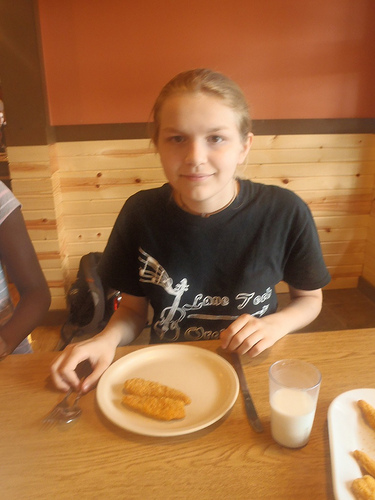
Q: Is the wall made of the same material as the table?
A: Yes, both the wall and the table are made of wood.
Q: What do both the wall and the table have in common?
A: The material, both the wall and the table are wooden.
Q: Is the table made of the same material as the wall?
A: Yes, both the table and the wall are made of wood.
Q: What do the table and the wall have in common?
A: The material, both the table and the wall are wooden.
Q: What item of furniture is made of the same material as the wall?
A: The table is made of the same material as the wall.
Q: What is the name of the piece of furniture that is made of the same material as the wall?
A: The piece of furniture is a table.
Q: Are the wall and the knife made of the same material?
A: No, the wall is made of wood and the knife is made of metal.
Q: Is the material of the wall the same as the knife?
A: No, the wall is made of wood and the knife is made of metal.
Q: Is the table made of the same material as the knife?
A: No, the table is made of wood and the knife is made of metal.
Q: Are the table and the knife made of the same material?
A: No, the table is made of wood and the knife is made of metal.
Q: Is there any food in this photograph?
A: Yes, there is food.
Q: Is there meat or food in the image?
A: Yes, there is food.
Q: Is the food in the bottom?
A: Yes, the food is in the bottom of the image.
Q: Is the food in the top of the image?
A: No, the food is in the bottom of the image.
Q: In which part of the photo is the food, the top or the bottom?
A: The food is in the bottom of the image.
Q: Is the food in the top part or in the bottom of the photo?
A: The food is in the bottom of the image.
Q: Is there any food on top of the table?
A: Yes, there is food on top of the table.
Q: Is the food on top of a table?
A: Yes, the food is on top of a table.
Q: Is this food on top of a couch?
A: No, the food is on top of a table.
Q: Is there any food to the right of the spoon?
A: Yes, there is food to the right of the spoon.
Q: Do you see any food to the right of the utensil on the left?
A: Yes, there is food to the right of the spoon.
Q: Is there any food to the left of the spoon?
A: No, the food is to the right of the spoon.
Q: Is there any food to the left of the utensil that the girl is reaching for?
A: No, the food is to the right of the spoon.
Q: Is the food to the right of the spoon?
A: Yes, the food is to the right of the spoon.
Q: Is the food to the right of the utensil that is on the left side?
A: Yes, the food is to the right of the spoon.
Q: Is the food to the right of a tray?
A: No, the food is to the right of the spoon.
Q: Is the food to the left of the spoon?
A: No, the food is to the right of the spoon.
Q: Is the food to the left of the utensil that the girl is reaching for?
A: No, the food is to the right of the spoon.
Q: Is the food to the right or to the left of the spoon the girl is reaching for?
A: The food is to the right of the spoon.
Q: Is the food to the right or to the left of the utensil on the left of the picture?
A: The food is to the right of the spoon.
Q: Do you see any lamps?
A: No, there are no lamps.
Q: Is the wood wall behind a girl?
A: Yes, the wall is behind a girl.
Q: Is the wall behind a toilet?
A: No, the wall is behind a girl.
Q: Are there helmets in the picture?
A: No, there are no helmets.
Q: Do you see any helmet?
A: No, there are no helmets.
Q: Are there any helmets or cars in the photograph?
A: No, there are no helmets or cars.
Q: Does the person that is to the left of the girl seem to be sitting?
A: Yes, the person is sitting.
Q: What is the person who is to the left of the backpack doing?
A: The person is sitting.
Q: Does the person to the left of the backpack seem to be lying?
A: No, the person is sitting.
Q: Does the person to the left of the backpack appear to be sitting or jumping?
A: The person is sitting.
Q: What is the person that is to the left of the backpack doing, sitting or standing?
A: The person is sitting.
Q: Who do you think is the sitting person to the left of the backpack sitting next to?
A: The person is sitting next to the girl.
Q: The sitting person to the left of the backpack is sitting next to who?
A: The person is sitting next to the girl.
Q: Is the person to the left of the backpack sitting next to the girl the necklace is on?
A: Yes, the person is sitting next to the girl.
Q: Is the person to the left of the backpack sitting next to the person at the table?
A: Yes, the person is sitting next to the girl.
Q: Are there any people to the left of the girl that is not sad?
A: Yes, there is a person to the left of the girl.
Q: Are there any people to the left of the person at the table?
A: Yes, there is a person to the left of the girl.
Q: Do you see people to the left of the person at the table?
A: Yes, there is a person to the left of the girl.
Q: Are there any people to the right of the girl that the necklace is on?
A: No, the person is to the left of the girl.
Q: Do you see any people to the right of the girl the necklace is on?
A: No, the person is to the left of the girl.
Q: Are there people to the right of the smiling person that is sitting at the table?
A: No, the person is to the left of the girl.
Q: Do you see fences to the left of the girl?
A: No, there is a person to the left of the girl.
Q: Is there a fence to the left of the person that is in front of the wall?
A: No, there is a person to the left of the girl.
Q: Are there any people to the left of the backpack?
A: Yes, there is a person to the left of the backpack.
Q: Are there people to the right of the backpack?
A: No, the person is to the left of the backpack.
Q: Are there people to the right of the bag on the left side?
A: No, the person is to the left of the backpack.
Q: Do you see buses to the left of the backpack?
A: No, there is a person to the left of the backpack.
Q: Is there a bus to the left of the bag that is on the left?
A: No, there is a person to the left of the backpack.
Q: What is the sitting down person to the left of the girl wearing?
A: The person is wearing a shirt.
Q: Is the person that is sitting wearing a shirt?
A: Yes, the person is wearing a shirt.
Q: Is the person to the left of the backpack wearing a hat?
A: No, the person is wearing a shirt.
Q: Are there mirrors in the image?
A: No, there are no mirrors.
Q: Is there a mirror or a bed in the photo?
A: No, there are no mirrors or beds.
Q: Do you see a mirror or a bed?
A: No, there are no mirrors or beds.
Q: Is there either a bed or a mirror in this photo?
A: No, there are no mirrors or beds.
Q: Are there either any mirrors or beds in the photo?
A: No, there are no mirrors or beds.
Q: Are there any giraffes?
A: No, there are no giraffes.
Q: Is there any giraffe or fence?
A: No, there are no giraffes or fences.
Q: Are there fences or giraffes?
A: No, there are no giraffes or fences.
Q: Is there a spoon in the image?
A: Yes, there is a spoon.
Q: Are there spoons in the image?
A: Yes, there is a spoon.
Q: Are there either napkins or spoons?
A: Yes, there is a spoon.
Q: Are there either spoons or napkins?
A: Yes, there is a spoon.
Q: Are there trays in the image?
A: No, there are no trays.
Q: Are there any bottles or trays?
A: No, there are no trays or bottles.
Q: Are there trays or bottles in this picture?
A: No, there are no trays or bottles.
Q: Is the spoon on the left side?
A: Yes, the spoon is on the left of the image.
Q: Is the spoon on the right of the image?
A: No, the spoon is on the left of the image.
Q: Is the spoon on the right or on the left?
A: The spoon is on the left of the image.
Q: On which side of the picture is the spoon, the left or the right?
A: The spoon is on the left of the image.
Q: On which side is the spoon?
A: The spoon is on the left of the image.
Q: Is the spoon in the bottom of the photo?
A: Yes, the spoon is in the bottom of the image.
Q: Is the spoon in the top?
A: No, the spoon is in the bottom of the image.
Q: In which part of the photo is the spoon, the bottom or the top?
A: The spoon is in the bottom of the image.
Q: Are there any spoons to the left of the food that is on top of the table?
A: Yes, there is a spoon to the left of the food.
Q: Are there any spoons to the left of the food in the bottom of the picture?
A: Yes, there is a spoon to the left of the food.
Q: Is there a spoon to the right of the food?
A: No, the spoon is to the left of the food.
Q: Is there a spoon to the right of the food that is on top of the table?
A: No, the spoon is to the left of the food.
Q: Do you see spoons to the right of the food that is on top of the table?
A: No, the spoon is to the left of the food.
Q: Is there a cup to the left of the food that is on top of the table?
A: No, there is a spoon to the left of the food.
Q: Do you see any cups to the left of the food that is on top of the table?
A: No, there is a spoon to the left of the food.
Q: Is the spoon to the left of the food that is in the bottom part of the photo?
A: Yes, the spoon is to the left of the food.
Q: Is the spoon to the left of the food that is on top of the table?
A: Yes, the spoon is to the left of the food.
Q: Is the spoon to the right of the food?
A: No, the spoon is to the left of the food.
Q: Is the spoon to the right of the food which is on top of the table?
A: No, the spoon is to the left of the food.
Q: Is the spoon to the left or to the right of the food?
A: The spoon is to the left of the food.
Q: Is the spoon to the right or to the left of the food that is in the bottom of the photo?
A: The spoon is to the left of the food.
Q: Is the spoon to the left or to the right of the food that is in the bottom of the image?
A: The spoon is to the left of the food.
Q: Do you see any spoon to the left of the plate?
A: Yes, there is a spoon to the left of the plate.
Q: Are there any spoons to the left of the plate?
A: Yes, there is a spoon to the left of the plate.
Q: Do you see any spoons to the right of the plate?
A: No, the spoon is to the left of the plate.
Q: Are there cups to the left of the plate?
A: No, there is a spoon to the left of the plate.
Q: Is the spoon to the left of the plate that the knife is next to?
A: Yes, the spoon is to the left of the plate.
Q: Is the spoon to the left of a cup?
A: No, the spoon is to the left of the plate.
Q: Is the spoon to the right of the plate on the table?
A: No, the spoon is to the left of the plate.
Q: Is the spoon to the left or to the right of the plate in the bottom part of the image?
A: The spoon is to the left of the plate.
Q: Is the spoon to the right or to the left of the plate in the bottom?
A: The spoon is to the left of the plate.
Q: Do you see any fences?
A: No, there are no fences.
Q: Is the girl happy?
A: Yes, the girl is happy.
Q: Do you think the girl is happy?
A: Yes, the girl is happy.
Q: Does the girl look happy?
A: Yes, the girl is happy.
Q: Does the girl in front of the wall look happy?
A: Yes, the girl is happy.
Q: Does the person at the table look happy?
A: Yes, the girl is happy.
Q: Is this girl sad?
A: No, the girl is happy.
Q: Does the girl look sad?
A: No, the girl is happy.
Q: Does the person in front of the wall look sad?
A: No, the girl is happy.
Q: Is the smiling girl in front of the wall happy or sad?
A: The girl is happy.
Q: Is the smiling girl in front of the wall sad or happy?
A: The girl is happy.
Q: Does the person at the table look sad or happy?
A: The girl is happy.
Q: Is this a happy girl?
A: Yes, this is a happy girl.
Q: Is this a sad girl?
A: No, this is a happy girl.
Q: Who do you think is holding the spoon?
A: The girl is holding the spoon.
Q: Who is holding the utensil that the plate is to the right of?
A: The girl is holding the spoon.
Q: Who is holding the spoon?
A: The girl is holding the spoon.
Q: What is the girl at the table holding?
A: The girl is holding the spoon.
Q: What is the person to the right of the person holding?
A: The girl is holding the spoon.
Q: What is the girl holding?
A: The girl is holding the spoon.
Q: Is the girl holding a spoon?
A: Yes, the girl is holding a spoon.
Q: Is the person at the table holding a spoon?
A: Yes, the girl is holding a spoon.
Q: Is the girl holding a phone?
A: No, the girl is holding a spoon.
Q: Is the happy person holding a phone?
A: No, the girl is holding a spoon.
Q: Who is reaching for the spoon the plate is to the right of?
A: The girl is reaching for the spoon.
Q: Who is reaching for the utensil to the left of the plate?
A: The girl is reaching for the spoon.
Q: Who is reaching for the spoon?
A: The girl is reaching for the spoon.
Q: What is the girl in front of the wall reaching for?
A: The girl is reaching for the spoon.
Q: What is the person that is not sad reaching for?
A: The girl is reaching for the spoon.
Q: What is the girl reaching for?
A: The girl is reaching for the spoon.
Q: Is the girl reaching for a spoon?
A: Yes, the girl is reaching for a spoon.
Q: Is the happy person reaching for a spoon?
A: Yes, the girl is reaching for a spoon.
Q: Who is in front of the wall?
A: The girl is in front of the wall.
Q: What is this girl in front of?
A: The girl is in front of the wall.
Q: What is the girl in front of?
A: The girl is in front of the wall.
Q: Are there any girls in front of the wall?
A: Yes, there is a girl in front of the wall.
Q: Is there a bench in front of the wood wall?
A: No, there is a girl in front of the wall.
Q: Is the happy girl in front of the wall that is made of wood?
A: Yes, the girl is in front of the wall.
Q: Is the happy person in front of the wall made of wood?
A: Yes, the girl is in front of the wall.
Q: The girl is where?
A: The girl is at the table.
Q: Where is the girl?
A: The girl is at the table.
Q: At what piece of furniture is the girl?
A: The girl is at the table.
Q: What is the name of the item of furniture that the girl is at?
A: The piece of furniture is a table.